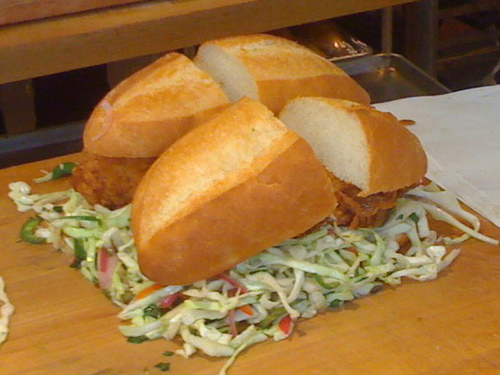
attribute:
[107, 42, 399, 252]
bread — cut, white, large, french, frenc, sliced, golden brown, soft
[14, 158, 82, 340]
board — brown, wooden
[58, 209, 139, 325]
lettuce — chopped, green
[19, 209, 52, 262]
pepper — green, sliced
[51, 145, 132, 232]
meat — brown, fried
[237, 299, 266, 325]
carrot — orange, small, sliced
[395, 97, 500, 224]
napkin — white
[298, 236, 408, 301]
cabbage — shredded, cut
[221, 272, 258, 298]
onion — purple, sliced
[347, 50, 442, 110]
tray — metal